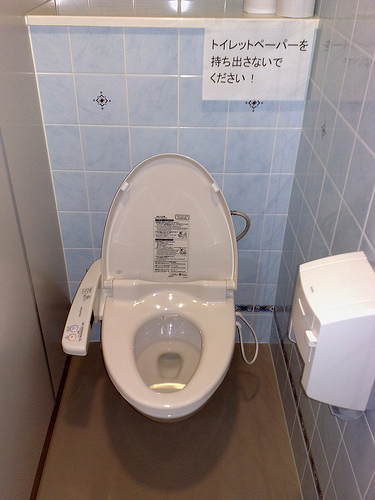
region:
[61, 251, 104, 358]
an arm rest on a toilet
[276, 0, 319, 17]
a roll of toilet paper on a bathroom shelf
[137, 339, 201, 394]
water in a toilet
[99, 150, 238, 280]
the lid of a toilet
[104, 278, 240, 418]
a white toilet seat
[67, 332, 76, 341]
a red button on an arm rest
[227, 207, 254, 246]
a flexible metal pipe running behind a toilet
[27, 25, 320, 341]
a light blue tile wall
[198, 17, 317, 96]
a paper sign taped to a shelf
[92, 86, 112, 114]
a black marking on a wall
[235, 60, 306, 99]
paper on the wall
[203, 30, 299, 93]
writing on the note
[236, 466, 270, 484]
the floor is wood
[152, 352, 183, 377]
drain of the toilet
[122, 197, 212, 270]
lid of the toilet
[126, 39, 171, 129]
tile on the wall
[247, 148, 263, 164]
the wall is blue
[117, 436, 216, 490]
shadow of the toilet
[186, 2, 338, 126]
this sign is in Japanese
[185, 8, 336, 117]
this is a white piece of paper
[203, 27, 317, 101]
black text on a piece of paper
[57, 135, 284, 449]
is is a toilet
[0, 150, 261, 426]
the seat is polycarbonate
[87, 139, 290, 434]
the lid is up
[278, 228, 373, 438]
a white toilet paper dispenser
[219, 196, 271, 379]
there are tubes for water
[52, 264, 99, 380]
the buttons to flush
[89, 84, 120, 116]
a black design on a blue tile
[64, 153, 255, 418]
a white electric toilet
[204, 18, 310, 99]
white paper sign with black print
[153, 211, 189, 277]
sticker on toilet lid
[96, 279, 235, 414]
white toilet seat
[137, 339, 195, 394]
water in toilet bowl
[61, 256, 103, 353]
arm rest on toilet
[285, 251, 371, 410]
white paper towel dispenser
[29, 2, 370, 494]
light blue tile walks with black accents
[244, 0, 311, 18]
two rolls of toilet paper on ledge above toilet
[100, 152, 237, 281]
white toilet lid is up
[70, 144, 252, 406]
the toilet seat is up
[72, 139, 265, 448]
the toilet seat is up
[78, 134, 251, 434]
the toilet seat is up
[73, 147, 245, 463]
the toilet seat is up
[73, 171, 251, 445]
the toilet seat is up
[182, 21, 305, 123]
a Japanese characters on paper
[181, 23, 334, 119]
a Japanese characters on paper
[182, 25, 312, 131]
a Japanese characters on paper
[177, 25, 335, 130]
a Japanese characters on paper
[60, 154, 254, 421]
toilet with seat up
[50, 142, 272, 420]
toilet with seat up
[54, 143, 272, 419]
toilet with seat up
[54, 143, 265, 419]
toilet with seat up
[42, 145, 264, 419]
toilet with seat up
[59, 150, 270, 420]
toilet with seat up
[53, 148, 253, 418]
toilet with seat up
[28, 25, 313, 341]
wall of square tiles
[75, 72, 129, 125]
decoration on square tile